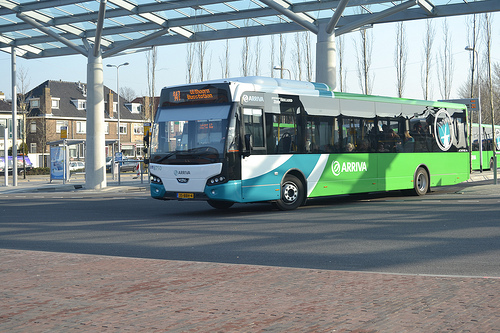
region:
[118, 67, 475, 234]
a green and blue bus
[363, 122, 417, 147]
people riding on a bus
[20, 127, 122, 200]
a bus stop shelter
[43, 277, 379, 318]
a brick road way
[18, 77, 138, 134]
a building with shingled roof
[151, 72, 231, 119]
digital letters and numbers on a bus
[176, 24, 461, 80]
a row of trees with no leaves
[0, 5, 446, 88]
a concrete canopy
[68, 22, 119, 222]
a concrete column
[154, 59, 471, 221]
a public transportation bus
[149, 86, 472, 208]
metro bus on street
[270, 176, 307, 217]
wheel on the bus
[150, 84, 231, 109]
electronic sign on top of bus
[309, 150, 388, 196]
logo on the bus side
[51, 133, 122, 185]
bus stop area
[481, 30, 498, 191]
tree on side of the road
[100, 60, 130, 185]
street light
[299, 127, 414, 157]
people on the bus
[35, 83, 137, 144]
large house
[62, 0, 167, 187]
metal structure at bus stop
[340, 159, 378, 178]
ARRIVA written on side of bus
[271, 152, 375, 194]
bus is light blue, green and white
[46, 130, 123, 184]
covered bus spot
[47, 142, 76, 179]
billboard on the side of bus stop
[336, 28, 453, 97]
trees have no leaves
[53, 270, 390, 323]
sidewalk is made of bricks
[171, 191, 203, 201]
license plate of bus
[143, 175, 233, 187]
bus has sets of three lights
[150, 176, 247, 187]
bus has six headlights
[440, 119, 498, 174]
two buses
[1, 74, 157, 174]
brick building in the background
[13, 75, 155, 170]
the brick on the house is brown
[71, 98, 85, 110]
windows coming out of the roof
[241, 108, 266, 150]
drivers window on the bus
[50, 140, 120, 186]
bus shelter for people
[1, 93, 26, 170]
white building beside brick building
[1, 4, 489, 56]
roof of shelter over road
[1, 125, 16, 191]
white post on the side of the road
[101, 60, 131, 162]
light posts on the side of the road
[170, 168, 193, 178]
writing on the front of the bus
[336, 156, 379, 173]
The bus company name is printed in white on the side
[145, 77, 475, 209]
the bus is white, teal, green and black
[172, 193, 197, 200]
the license plate is yellow and blue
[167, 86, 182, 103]
the bus number is 41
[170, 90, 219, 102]
the route is in orange print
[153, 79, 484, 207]
the bus is parked at the bus terminal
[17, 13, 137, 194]
cement pillers holding up covering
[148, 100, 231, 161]
window on the front of the bus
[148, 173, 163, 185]
headlights on the front of the bus